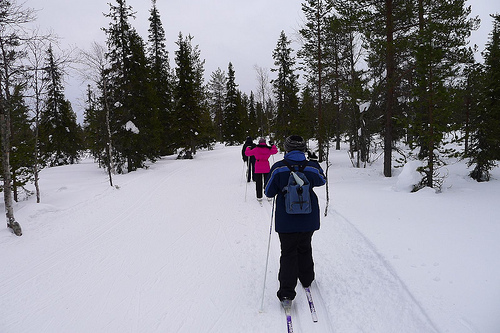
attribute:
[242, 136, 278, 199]
skier — skiing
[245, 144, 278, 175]
coat — pink, bright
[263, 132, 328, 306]
skier — skiing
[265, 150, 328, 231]
coat — black, blue, striped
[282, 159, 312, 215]
backpack — black, blue, small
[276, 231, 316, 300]
pants — warm, black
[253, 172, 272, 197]
pants — warm, black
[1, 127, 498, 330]
ground — snowy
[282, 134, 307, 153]
cap — black, knitted, knit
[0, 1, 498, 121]
sky — overcast, beautiful, wintry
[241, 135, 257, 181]
skier — skiing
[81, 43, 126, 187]
tree — dead, growing, bare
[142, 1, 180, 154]
tree — beautiful, green, growing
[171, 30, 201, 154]
tree — beautiful, green, growing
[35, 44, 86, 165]
tree — beautiful, green, growing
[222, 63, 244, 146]
tree — beautiful, green, growing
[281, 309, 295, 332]
ski — purple, white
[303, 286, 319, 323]
ski — purple, white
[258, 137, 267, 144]
cap — grey